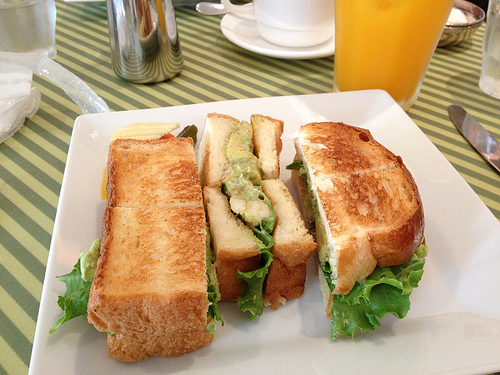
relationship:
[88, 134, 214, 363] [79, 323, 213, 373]
toast casting shadow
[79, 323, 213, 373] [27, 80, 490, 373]
shadow on plate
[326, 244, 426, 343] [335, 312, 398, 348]
lettuce casting shadow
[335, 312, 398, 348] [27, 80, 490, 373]
shadow on plate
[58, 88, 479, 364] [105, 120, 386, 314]
plate full of food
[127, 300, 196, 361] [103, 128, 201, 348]
crust of some bread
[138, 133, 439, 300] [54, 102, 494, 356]
sandwich on plate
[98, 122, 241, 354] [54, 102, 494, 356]
sandwich on plate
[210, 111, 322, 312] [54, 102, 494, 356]
sandwich on plate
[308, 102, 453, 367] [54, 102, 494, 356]
sandwich on plate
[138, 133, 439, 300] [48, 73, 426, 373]
sandwich on plate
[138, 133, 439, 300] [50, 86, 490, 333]
sandwich on plate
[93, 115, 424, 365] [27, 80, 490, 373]
portions are on plate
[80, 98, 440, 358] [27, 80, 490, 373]
portions are on plate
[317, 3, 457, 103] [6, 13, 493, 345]
glass on table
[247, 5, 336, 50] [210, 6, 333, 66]
cup on plate